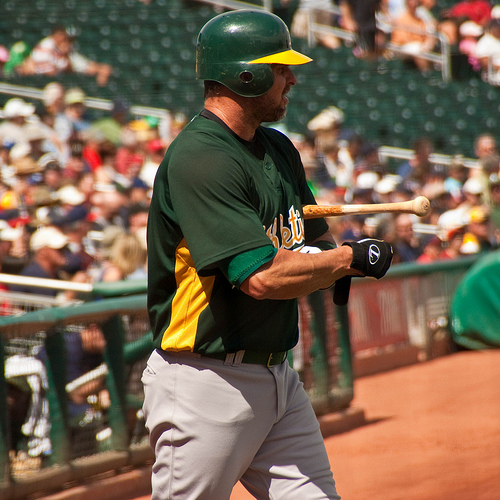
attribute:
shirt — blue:
[393, 237, 423, 261]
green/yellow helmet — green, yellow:
[178, 10, 313, 102]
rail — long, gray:
[214, 1, 458, 85]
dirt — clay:
[401, 397, 490, 472]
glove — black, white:
[342, 227, 407, 287]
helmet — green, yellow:
[185, 5, 316, 77]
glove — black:
[340, 239, 405, 282]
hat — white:
[24, 223, 72, 255]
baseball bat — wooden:
[300, 190, 435, 217]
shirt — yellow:
[131, 113, 335, 360]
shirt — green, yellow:
[135, 107, 342, 372]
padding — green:
[6, 293, 150, 457]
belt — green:
[215, 347, 289, 366]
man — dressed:
[139, 8, 398, 499]